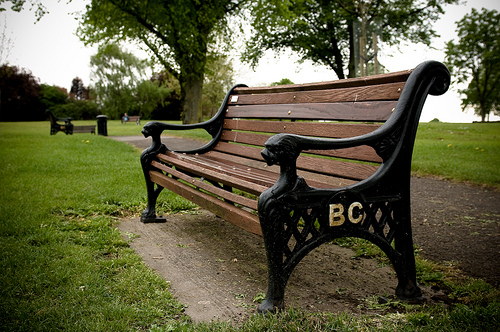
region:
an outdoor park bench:
[136, 55, 457, 310]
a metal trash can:
[93, 112, 110, 135]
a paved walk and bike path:
[98, 128, 492, 278]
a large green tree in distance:
[81, 5, 230, 116]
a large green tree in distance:
[254, 0, 426, 88]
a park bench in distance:
[44, 114, 78, 134]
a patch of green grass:
[6, 117, 195, 330]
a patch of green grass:
[415, 119, 499, 179]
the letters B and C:
[324, 196, 367, 228]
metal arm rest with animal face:
[254, 130, 295, 170]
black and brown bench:
[120, 58, 450, 315]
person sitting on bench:
[112, 101, 142, 131]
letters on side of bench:
[316, 195, 371, 233]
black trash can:
[95, 108, 113, 138]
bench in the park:
[146, 48, 435, 305]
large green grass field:
[6, 132, 133, 216]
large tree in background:
[114, 2, 246, 118]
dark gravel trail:
[421, 178, 491, 260]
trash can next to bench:
[91, 103, 115, 139]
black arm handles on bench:
[261, 126, 306, 176]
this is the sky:
[36, 33, 63, 61]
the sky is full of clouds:
[25, 35, 67, 70]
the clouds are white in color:
[37, 35, 68, 69]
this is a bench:
[115, 60, 460, 308]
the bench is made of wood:
[243, 105, 311, 130]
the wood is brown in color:
[236, 90, 316, 133]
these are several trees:
[79, 0, 492, 55]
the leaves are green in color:
[84, 7, 129, 37]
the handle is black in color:
[389, 155, 401, 180]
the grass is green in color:
[31, 182, 98, 295]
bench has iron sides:
[145, 80, 497, 256]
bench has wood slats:
[167, 82, 353, 269]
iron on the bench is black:
[225, 120, 458, 317]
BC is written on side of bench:
[333, 200, 383, 236]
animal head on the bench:
[262, 129, 305, 178]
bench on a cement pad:
[94, 183, 438, 320]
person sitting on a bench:
[104, 99, 157, 129]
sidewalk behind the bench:
[310, 109, 497, 318]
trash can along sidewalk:
[87, 109, 126, 139]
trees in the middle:
[99, 48, 494, 85]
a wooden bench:
[129, 54, 466, 322]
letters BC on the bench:
[320, 187, 385, 248]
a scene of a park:
[9, 5, 496, 307]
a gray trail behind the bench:
[117, 122, 497, 257]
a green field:
[12, 127, 493, 325]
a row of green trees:
[72, 4, 497, 149]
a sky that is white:
[5, 2, 495, 122]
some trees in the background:
[0, 60, 231, 131]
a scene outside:
[17, 14, 498, 316]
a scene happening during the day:
[10, 8, 498, 319]